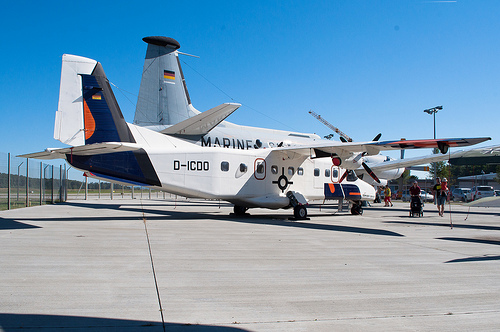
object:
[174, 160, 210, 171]
figures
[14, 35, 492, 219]
planes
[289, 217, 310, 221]
wheel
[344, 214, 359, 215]
wheel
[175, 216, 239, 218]
gray plane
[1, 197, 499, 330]
parking lot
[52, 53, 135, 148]
wing plane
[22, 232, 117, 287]
concrete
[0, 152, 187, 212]
fence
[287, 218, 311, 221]
wheel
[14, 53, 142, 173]
tail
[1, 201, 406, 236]
plane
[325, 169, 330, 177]
window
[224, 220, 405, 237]
wing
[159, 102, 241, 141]
wing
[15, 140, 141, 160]
wing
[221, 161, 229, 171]
window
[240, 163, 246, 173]
window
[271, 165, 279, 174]
window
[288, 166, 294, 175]
window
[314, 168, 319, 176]
window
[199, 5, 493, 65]
sky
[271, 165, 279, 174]
passenger window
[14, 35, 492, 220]
white plane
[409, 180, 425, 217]
people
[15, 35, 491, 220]
airplane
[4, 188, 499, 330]
lot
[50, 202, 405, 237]
plane wing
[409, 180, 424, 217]
woman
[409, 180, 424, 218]
stroller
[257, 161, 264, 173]
window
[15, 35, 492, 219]
body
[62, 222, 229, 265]
plane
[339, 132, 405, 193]
fencing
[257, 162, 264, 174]
window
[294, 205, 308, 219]
plane wheel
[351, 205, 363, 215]
plane wheel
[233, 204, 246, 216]
plane wheel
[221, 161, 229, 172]
passenger window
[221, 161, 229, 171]
passenger window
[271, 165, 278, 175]
passenger window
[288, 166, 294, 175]
passenger window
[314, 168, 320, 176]
passenger window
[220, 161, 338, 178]
windows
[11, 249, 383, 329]
ground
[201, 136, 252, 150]
word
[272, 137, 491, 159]
wing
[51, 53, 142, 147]
wing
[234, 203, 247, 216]
wheel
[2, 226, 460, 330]
ground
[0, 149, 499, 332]
airport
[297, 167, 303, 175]
window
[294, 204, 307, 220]
wheel